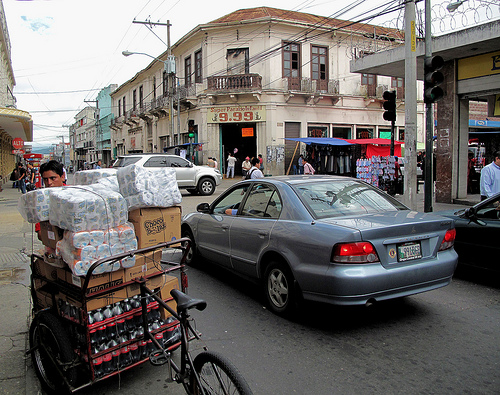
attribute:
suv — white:
[74, 148, 224, 195]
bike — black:
[73, 262, 211, 368]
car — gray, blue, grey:
[185, 175, 455, 312]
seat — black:
[168, 285, 208, 314]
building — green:
[91, 88, 116, 159]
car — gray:
[283, 175, 383, 280]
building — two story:
[109, 5, 424, 177]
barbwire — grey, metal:
[421, 2, 498, 40]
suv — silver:
[182, 183, 478, 324]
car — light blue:
[186, 187, 420, 311]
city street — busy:
[177, 174, 498, 393]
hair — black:
[38, 158, 65, 178]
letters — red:
[206, 103, 265, 112]